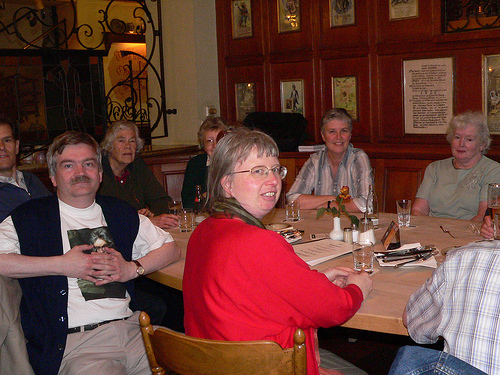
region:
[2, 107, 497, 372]
People sitting around a wooden table.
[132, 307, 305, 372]
The back of a brown wooden chair.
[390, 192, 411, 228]
Clear liquid in a clear glass.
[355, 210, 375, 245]
Salt in a clear salt shaker.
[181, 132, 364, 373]
A woman wearing a red shirt.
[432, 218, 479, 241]
A pair of glasses on the table.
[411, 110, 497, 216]
A woman wearing a green shirt.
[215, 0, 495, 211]
A wooden wall.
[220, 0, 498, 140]
Framed pictures on the wooden wall.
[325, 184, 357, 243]
Red flowers in a small white vase.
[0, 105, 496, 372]
eight people sitting at a table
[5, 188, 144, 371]
a man wearing a blue sweater vest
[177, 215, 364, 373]
a woman wearing a red shirt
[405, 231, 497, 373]
a person wearing a plaid shirt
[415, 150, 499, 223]
a woman wearing a green shirt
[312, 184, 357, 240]
a white vase with a flower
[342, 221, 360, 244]
a salt and a pepper shaker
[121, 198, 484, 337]
a light brown table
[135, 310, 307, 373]
a brown wooden chair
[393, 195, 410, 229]
a glass of water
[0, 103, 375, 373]
People sitting at a table.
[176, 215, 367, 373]
Woman wearing red sweater.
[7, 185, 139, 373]
Man wearing navy blue vest.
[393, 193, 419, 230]
Glass of water sitting on table.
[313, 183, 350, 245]
Vase with flower sitting on table.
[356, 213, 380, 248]
Sugar container sitting on table.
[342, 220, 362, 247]
Salt and pepper shakers sitting on table.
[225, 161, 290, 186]
Woman wearing eyeglasses over eyes.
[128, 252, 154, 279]
Man wearing watch on wrist.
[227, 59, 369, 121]
Pictures on wall behind table with people.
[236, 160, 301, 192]
woman wearing glasses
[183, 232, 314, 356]
woman with a red shirt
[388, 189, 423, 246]
glass with water on a table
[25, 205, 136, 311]
man with a blue vest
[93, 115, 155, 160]
woman with grey hair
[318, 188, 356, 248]
rose inside in a vase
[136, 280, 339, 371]
woman sitting in a wooden chair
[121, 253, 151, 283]
man with a wrist watch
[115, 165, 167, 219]
woman with green shirt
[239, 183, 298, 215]
woman with a smile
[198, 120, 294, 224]
The head of a woman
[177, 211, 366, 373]
The woman is wearing a red sweater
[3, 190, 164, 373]
The man is sitting in the chair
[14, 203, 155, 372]
The man is wearing a blue vest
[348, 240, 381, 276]
The glass of water on the table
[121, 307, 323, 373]
The chair is brown and wooden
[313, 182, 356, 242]
The vase on the table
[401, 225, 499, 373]
The man is wearing a plaid shirt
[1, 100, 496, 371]
The group is looking forward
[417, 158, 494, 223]
The woman is wearing a gray shirt